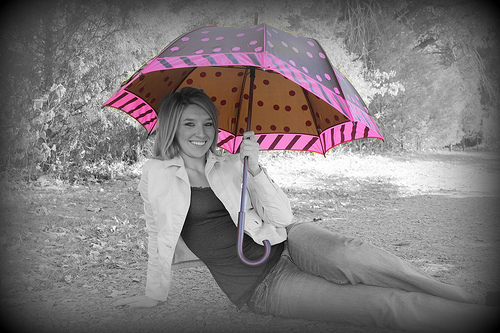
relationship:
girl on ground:
[128, 86, 499, 332] [2, 159, 499, 328]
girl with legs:
[128, 86, 499, 332] [247, 222, 498, 332]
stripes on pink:
[275, 132, 296, 149] [280, 137, 290, 143]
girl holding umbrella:
[128, 86, 499, 332] [99, 14, 386, 266]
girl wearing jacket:
[128, 86, 499, 332] [139, 153, 293, 301]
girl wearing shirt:
[128, 86, 499, 332] [169, 157, 278, 309]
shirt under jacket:
[169, 157, 278, 309] [139, 153, 293, 301]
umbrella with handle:
[99, 14, 386, 266] [227, 209, 277, 269]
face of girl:
[174, 102, 218, 162] [128, 86, 499, 332]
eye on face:
[182, 121, 199, 126] [174, 102, 218, 162]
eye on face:
[203, 118, 213, 129] [174, 102, 218, 162]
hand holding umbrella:
[236, 133, 263, 169] [99, 14, 386, 266]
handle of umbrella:
[227, 209, 277, 269] [99, 14, 386, 266]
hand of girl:
[236, 133, 263, 169] [128, 86, 499, 332]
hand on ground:
[106, 293, 166, 309] [2, 159, 499, 328]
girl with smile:
[128, 86, 499, 332] [194, 142, 204, 145]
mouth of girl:
[187, 137, 210, 149] [128, 86, 499, 332]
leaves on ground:
[34, 202, 152, 300] [2, 159, 499, 328]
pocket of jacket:
[244, 214, 280, 238] [139, 153, 293, 301]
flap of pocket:
[242, 216, 266, 232] [244, 214, 280, 238]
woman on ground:
[128, 86, 499, 332] [2, 159, 499, 328]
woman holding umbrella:
[128, 86, 499, 332] [99, 14, 386, 266]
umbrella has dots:
[99, 14, 386, 266] [287, 43, 316, 77]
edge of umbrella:
[265, 64, 305, 95] [99, 14, 386, 266]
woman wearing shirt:
[128, 86, 499, 332] [169, 157, 278, 309]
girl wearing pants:
[110, 86, 500, 329] [247, 204, 499, 333]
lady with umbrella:
[128, 86, 499, 332] [99, 14, 386, 266]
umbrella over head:
[99, 14, 386, 266] [152, 87, 233, 171]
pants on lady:
[247, 204, 499, 333] [128, 86, 499, 332]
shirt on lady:
[169, 157, 278, 309] [128, 86, 499, 332]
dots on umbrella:
[287, 43, 316, 77] [99, 14, 386, 266]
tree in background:
[13, 6, 126, 186] [8, 9, 487, 169]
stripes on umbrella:
[275, 132, 296, 149] [99, 14, 386, 266]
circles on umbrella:
[287, 43, 316, 77] [99, 14, 386, 266]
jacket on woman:
[139, 153, 293, 301] [128, 86, 499, 332]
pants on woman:
[247, 204, 499, 333] [128, 86, 499, 332]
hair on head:
[155, 86, 197, 159] [152, 87, 233, 171]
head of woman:
[152, 87, 233, 171] [128, 86, 499, 332]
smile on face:
[194, 142, 204, 145] [174, 102, 218, 162]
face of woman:
[174, 102, 218, 162] [128, 86, 499, 332]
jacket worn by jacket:
[136, 152, 297, 300] [139, 153, 293, 301]